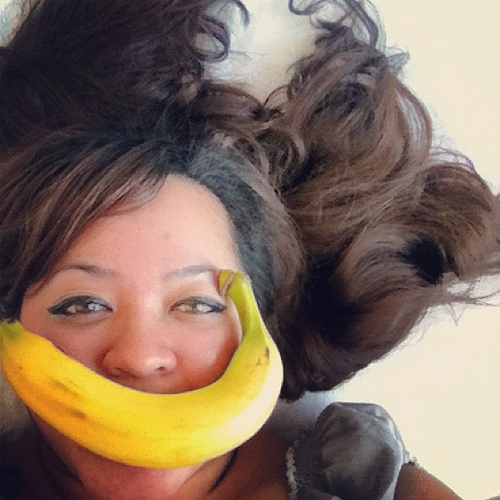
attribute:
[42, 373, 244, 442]
banana — yellow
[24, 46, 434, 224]
hair — brown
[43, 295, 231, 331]
eyes — brown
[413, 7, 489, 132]
sheets — white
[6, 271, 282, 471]
peel — yellow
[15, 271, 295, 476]
banana — ripe, yellow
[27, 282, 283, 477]
banana — yellow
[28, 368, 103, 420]
spot — brown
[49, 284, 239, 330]
eyes — brown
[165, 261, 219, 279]
eyebrows — brown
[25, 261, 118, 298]
eyebrows — brown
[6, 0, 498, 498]
surface — white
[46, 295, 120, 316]
eye — brown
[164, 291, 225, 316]
eye — brown